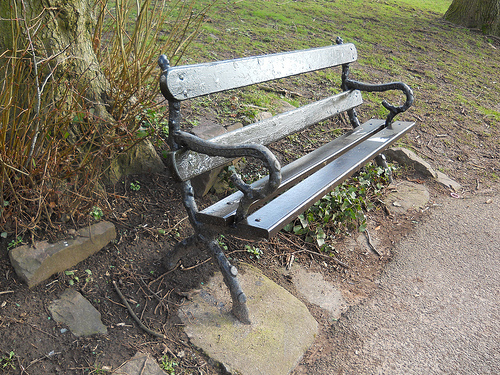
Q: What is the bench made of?
A: Metal and wood.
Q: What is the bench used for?
A: To sit.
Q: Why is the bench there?
A: For people to sit.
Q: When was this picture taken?
A: During the daytime.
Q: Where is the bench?
A: On the ground.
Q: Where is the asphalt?
A: In front of the bench.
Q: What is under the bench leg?
A: A cement block.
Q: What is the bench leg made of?
A: Metal.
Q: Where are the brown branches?
A: Behind the bench.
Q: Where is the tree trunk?
A: Behind the bench.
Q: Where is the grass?
A: Behind the bench.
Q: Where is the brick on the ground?
A: In front of the tree trunk.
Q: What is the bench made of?
A: Wood and metal.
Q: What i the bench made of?
A: Metal.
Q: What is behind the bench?
A: A tree trunk.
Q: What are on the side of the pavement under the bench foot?
A: Rocks.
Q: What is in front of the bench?
A: Pavement.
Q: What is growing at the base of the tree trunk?
A: Sticks.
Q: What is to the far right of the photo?
A: A tree trunk.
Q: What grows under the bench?
A: Leaves.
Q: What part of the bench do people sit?
A: The seat.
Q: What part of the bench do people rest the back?
A: The back rest.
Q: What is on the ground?
A: The bench.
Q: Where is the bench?
A: On the ground.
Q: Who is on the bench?
A: No people.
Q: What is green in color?
A: Grass.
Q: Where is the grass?
A: On the ground.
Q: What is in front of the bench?
A: Street.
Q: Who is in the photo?
A: No people.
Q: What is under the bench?
A: Leaves.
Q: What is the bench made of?
A: Metal.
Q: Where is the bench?
A: By a pathway.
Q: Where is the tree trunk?
A: Behind the bench.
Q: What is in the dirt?
A: Twigs and rocks.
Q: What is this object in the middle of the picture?
A: A bench.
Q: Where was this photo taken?
A: At the park.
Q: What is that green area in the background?
A: The grass.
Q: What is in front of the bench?
A: Pavement.